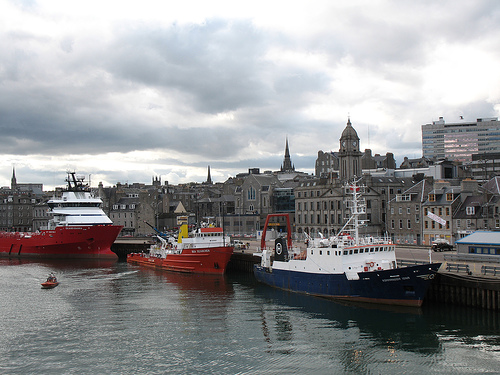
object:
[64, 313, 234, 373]
ripples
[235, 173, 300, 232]
building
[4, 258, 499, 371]
forefront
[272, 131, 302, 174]
background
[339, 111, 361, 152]
top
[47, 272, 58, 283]
person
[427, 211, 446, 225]
sign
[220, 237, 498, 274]
road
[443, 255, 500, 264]
railing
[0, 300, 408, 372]
water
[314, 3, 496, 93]
clouds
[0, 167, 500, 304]
port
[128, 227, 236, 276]
boats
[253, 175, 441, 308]
boat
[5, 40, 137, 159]
cloud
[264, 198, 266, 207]
window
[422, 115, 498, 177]
building